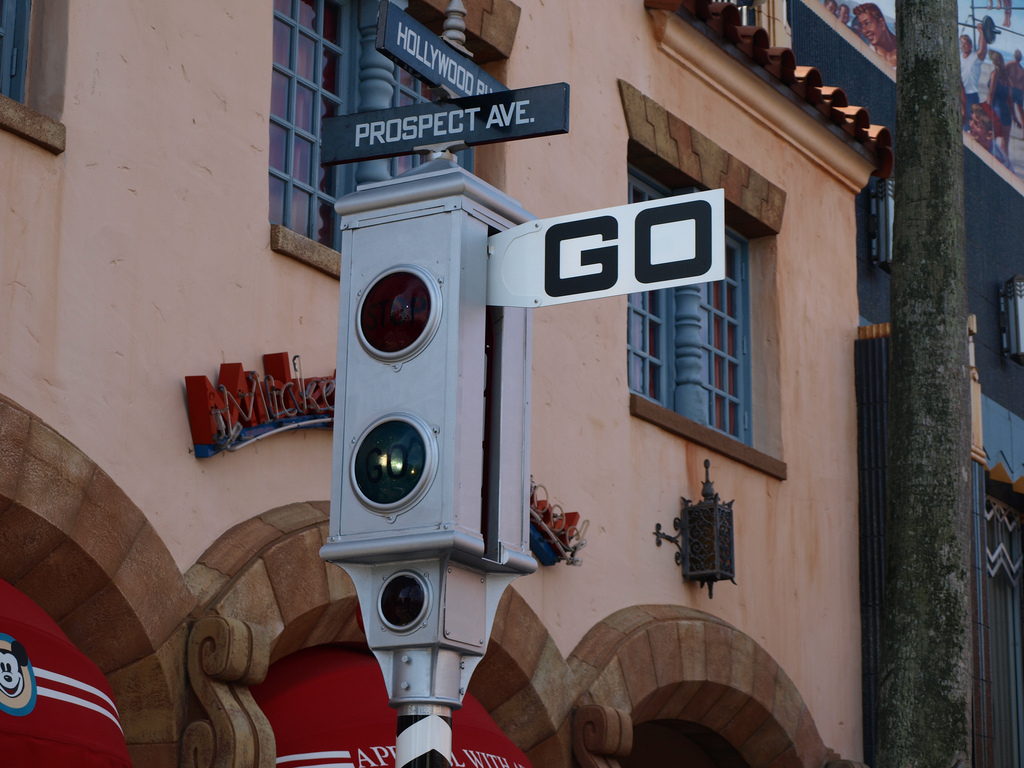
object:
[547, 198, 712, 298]
word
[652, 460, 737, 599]
lamp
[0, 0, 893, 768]
building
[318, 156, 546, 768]
post